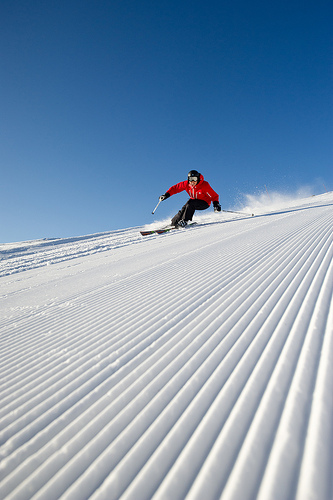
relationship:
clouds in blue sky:
[235, 46, 293, 81] [2, 0, 332, 248]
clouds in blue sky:
[42, 29, 75, 64] [106, 21, 262, 65]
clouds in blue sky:
[25, 94, 62, 129] [0, 0, 332, 246]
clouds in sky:
[47, 129, 91, 170] [4, 8, 321, 152]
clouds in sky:
[12, 167, 45, 195] [2, 3, 329, 167]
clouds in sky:
[99, 67, 131, 95] [86, 67, 137, 94]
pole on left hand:
[213, 199, 256, 224] [200, 179, 218, 206]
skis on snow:
[139, 220, 198, 234] [0, 191, 332, 499]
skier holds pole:
[159, 168, 221, 223] [214, 209, 254, 216]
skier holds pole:
[159, 168, 221, 223] [152, 201, 161, 215]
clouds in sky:
[75, 171, 109, 201] [2, 3, 329, 167]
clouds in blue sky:
[11, 125, 93, 167] [0, 0, 332, 246]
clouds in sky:
[216, 34, 281, 66] [3, 3, 332, 208]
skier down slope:
[159, 168, 221, 223] [2, 240, 331, 499]